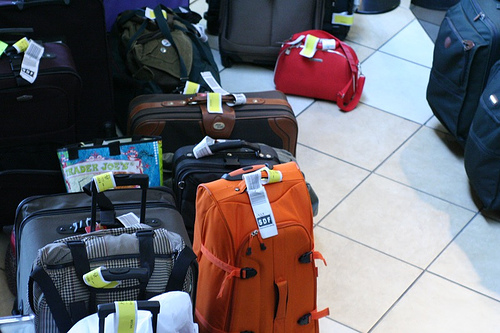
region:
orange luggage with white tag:
[192, 160, 342, 328]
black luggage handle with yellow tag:
[74, 266, 167, 293]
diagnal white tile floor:
[342, 152, 464, 302]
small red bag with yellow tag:
[270, 27, 369, 108]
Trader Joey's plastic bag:
[49, 123, 173, 185]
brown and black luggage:
[129, 81, 300, 141]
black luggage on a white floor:
[407, 6, 484, 156]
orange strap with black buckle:
[201, 243, 264, 285]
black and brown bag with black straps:
[112, 12, 245, 81]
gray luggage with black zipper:
[14, 187, 192, 266]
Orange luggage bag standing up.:
[189, 167, 322, 331]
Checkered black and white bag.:
[24, 220, 198, 332]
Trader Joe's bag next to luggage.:
[53, 131, 168, 193]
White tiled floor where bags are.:
[175, 0, 497, 332]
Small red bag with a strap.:
[268, 26, 371, 113]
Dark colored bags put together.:
[6, 6, 499, 305]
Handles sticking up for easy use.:
[83, 169, 163, 329]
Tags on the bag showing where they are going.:
[16, 5, 338, 332]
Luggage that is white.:
[64, 286, 199, 332]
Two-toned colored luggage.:
[125, 80, 307, 160]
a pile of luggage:
[16, 13, 406, 318]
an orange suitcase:
[177, 155, 346, 331]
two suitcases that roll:
[171, 135, 351, 331]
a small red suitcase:
[270, 0, 390, 115]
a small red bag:
[235, 10, 407, 135]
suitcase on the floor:
[7, 10, 463, 330]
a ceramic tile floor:
[265, 106, 495, 301]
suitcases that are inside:
[5, 8, 426, 329]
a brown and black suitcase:
[115, 70, 328, 161]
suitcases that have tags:
[5, 23, 442, 330]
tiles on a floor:
[343, 188, 468, 319]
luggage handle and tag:
[220, 160, 281, 225]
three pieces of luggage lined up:
[11, 182, 181, 327]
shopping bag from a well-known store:
[55, 127, 165, 184]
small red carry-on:
[275, 20, 365, 105]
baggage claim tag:
[15, 36, 45, 81]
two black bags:
[421, 1, 496, 211]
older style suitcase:
[127, 85, 297, 140]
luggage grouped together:
[21, 65, 318, 325]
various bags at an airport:
[112, 7, 487, 322]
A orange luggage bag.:
[190, 160, 315, 332]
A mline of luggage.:
[12, 181, 199, 332]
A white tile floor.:
[333, 117, 435, 327]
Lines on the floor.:
[342, 156, 428, 331]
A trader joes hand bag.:
[53, 126, 165, 191]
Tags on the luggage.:
[8, 31, 45, 81]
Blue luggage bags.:
[413, 2, 499, 236]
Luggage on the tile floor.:
[16, 0, 498, 332]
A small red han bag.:
[260, 22, 372, 110]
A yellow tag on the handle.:
[110, 298, 145, 330]